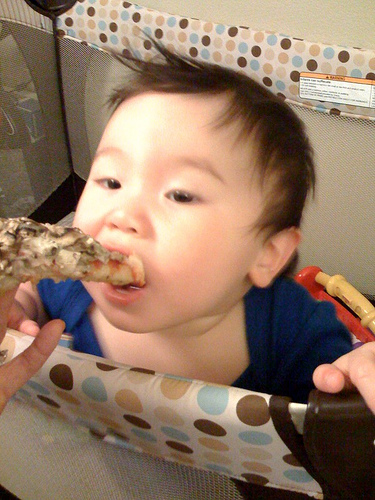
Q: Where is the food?
A: In the baby's mouth.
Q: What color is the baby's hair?
A: Dark brown.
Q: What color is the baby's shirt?
A: Blue.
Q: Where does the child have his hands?
A: On the edge of the cot.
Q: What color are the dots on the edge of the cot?
A: Blue beige and brown.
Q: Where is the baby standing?
A: In a travel cot.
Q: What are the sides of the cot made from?
A: Mesh material.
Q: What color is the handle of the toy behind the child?
A: Yellow.